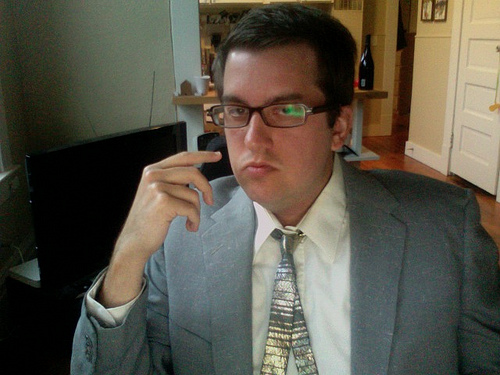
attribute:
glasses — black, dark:
[208, 100, 353, 129]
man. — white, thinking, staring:
[68, 4, 499, 374]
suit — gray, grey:
[69, 152, 498, 375]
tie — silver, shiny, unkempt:
[260, 228, 319, 374]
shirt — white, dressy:
[252, 151, 352, 374]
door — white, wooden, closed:
[448, 0, 499, 198]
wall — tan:
[0, 1, 174, 278]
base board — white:
[404, 140, 450, 177]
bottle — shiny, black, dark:
[358, 33, 374, 92]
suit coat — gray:
[71, 156, 500, 374]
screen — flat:
[25, 121, 187, 295]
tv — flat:
[21, 118, 189, 303]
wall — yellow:
[406, 1, 453, 157]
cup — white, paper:
[194, 74, 211, 97]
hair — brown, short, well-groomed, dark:
[212, 3, 355, 130]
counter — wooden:
[170, 80, 390, 105]